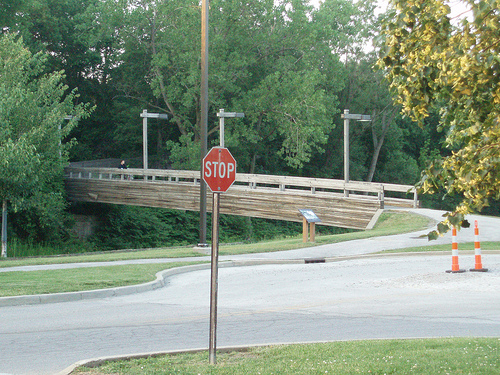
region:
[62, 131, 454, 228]
Pedestrian wooden footbridge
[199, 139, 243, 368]
Octagonal corner stop sign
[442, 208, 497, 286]
Construction orange white cones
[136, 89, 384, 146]
Three street lamps bridge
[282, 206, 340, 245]
Tourist information plaque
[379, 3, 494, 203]
Tree leaves beginning turn color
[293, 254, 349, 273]
Sewer drain water runoff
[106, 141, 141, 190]
Lone pedestrian crossing bridge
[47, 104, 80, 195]
Additional bridge lamp camouflaged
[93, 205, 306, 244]
Water area beneath bridge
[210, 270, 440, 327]
street is grey and concrete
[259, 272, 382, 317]
street is grey and concrete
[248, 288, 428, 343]
street is grey and concrete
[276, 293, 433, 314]
street is grey and concrete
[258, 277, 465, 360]
street is grey and concrete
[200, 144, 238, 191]
A red octagonal stop sign.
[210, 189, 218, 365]
A metal pole of the stop sign.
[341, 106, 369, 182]
An inactive street light.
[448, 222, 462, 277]
Orange and white safety cone.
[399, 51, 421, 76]
Green leaves on a tree.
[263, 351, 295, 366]
Green grass on a field.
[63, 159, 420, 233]
A sturdy wooden bridge.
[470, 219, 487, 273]
A different orange and white safety cone.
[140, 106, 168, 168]
A bridge light.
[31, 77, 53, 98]
Green leaves on a different kind of tree.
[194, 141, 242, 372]
stop sign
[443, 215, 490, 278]
2 thin construction cones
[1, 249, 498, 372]
smoothly paved road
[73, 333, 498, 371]
green grass with white flowers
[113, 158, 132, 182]
person walking on bridge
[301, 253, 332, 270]
sewer in the curb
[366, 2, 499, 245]
green and yellow leaves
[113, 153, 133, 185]
person wearing black shirt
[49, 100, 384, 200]
four unlit lamps on bridge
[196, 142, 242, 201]
red octagon sign with white letters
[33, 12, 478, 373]
Picture taken outside.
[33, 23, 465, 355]
Picture taken during the day.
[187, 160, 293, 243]
A stop sign.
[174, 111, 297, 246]
The sign is red and white.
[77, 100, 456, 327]
A bridge is shown.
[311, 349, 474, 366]
The grass is green.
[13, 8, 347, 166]
The trees are full of leaves.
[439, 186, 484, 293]
Two orange and white cones.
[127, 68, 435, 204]
Lights on the bridge.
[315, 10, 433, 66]
The sky is light grey in color.